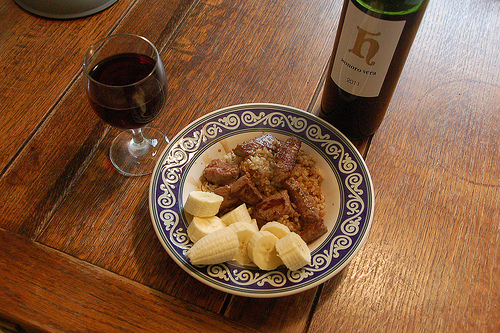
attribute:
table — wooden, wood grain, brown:
[0, 0, 500, 332]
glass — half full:
[81, 30, 176, 178]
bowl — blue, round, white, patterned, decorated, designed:
[149, 103, 377, 300]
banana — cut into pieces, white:
[182, 188, 315, 273]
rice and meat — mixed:
[200, 131, 331, 240]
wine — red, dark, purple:
[89, 50, 167, 127]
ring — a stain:
[415, 73, 499, 190]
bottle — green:
[322, 0, 431, 129]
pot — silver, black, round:
[8, 0, 125, 21]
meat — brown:
[272, 132, 302, 181]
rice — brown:
[242, 144, 280, 196]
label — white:
[330, 0, 406, 98]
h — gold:
[348, 24, 382, 66]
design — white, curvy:
[157, 111, 365, 291]